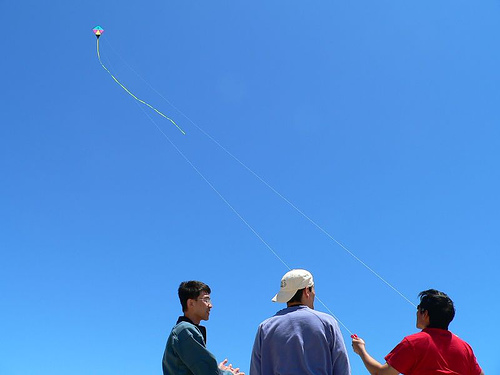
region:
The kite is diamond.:
[91, 19, 106, 40]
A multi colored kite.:
[88, 20, 107, 45]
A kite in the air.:
[80, 18, 110, 43]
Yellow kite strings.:
[96, 38, 191, 138]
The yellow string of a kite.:
[96, 36, 188, 136]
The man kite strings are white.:
[84, 35, 427, 339]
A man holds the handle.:
[349, 330, 364, 346]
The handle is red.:
[350, 330, 360, 342]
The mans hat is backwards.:
[267, 258, 317, 305]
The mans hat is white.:
[263, 259, 319, 306]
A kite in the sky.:
[78, 18, 115, 44]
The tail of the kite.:
[90, 37, 190, 137]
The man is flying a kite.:
[345, 265, 480, 370]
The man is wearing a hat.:
[260, 265, 316, 311]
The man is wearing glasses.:
[177, 280, 212, 322]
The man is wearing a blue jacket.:
[156, 310, 236, 370]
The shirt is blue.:
[246, 305, 351, 371]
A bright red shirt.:
[385, 325, 485, 372]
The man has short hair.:
[410, 280, 460, 335]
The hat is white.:
[268, 261, 316, 308]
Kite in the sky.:
[74, 17, 196, 128]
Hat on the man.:
[262, 238, 356, 331]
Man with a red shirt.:
[359, 305, 448, 372]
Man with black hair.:
[144, 265, 257, 324]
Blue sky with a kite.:
[115, 87, 461, 292]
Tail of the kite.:
[70, 35, 200, 202]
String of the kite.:
[118, 60, 333, 261]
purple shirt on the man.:
[237, 283, 353, 368]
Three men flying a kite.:
[137, 242, 496, 370]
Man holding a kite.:
[330, 307, 417, 370]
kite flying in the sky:
[72, 14, 203, 152]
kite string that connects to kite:
[343, 323, 368, 356]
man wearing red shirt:
[348, 265, 490, 371]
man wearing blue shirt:
[239, 255, 338, 371]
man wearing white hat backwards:
[261, 265, 326, 314]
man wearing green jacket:
[156, 272, 239, 372]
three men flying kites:
[146, 268, 490, 373]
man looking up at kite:
[335, 263, 483, 373]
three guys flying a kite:
[4, 8, 494, 373]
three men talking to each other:
[158, 268, 498, 368]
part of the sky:
[152, 212, 164, 226]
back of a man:
[296, 330, 298, 335]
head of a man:
[438, 304, 446, 320]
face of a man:
[193, 284, 204, 318]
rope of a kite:
[244, 215, 250, 252]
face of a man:
[306, 291, 308, 298]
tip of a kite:
[160, 120, 180, 125]